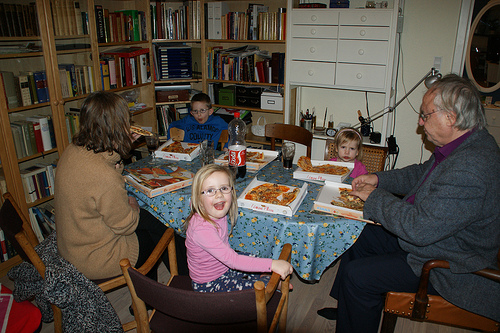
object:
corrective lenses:
[198, 184, 233, 194]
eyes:
[207, 188, 216, 193]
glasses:
[420, 107, 446, 122]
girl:
[178, 163, 297, 294]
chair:
[118, 226, 298, 331]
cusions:
[146, 272, 281, 333]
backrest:
[120, 261, 258, 332]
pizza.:
[222, 153, 231, 160]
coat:
[360, 130, 498, 322]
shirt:
[320, 158, 373, 179]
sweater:
[8, 227, 125, 333]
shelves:
[284, 0, 399, 149]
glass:
[197, 140, 217, 153]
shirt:
[181, 216, 275, 284]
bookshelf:
[0, 0, 285, 245]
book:
[139, 52, 149, 82]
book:
[128, 56, 138, 86]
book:
[85, 62, 98, 93]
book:
[80, 64, 92, 92]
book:
[29, 114, 54, 154]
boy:
[169, 91, 235, 149]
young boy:
[167, 92, 234, 144]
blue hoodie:
[168, 114, 230, 147]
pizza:
[157, 140, 199, 156]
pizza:
[295, 155, 351, 176]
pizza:
[247, 151, 269, 163]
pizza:
[330, 187, 365, 212]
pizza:
[127, 161, 194, 191]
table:
[126, 147, 374, 280]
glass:
[280, 140, 295, 170]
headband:
[334, 128, 361, 140]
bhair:
[184, 183, 203, 218]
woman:
[53, 89, 176, 316]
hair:
[95, 107, 113, 132]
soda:
[226, 151, 244, 181]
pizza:
[242, 182, 301, 207]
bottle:
[222, 110, 252, 180]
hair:
[229, 205, 240, 226]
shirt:
[167, 113, 232, 147]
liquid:
[283, 157, 291, 167]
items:
[300, 106, 383, 144]